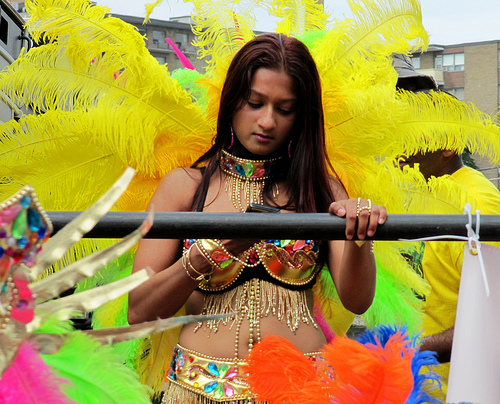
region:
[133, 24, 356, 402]
woman looking at a phone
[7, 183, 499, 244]
black metal pole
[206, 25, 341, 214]
woman with long dark hair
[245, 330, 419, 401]
fuzzy orange feathers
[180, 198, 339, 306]
golden bra with multicolored gems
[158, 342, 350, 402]
gold belt and skirt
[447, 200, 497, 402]
paper zip tied to the pole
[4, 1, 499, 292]
woman wearing a tail piece of yellow feathers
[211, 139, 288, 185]
gold necklace with colorful gems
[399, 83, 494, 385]
person wearing a yellow T-shirt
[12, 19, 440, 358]
the woman is wearing feathers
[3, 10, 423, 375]
the feathers are multi colored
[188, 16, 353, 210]
woman`s hair is reddish brown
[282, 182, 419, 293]
woman is holding a pole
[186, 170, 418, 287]
the pole is black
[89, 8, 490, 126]
a building in the background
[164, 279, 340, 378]
the woman`s stomach is showing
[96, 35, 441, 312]
the woman is looking at her phone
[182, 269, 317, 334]
woman is wearing gold beads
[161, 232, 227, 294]
the woman is wearing bracelets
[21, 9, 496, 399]
Woman dressed in an elaborate costume.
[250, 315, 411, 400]
Orange ornamental plumes.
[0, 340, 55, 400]
Pink ornamental plumes.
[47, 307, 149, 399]
Green ornamental plumes.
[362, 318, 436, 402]
Blue ornamental plumes.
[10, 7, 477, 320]
Yellow ornamental plumes.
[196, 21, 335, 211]
A woman with dark hair.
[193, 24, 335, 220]
A woman with long hair.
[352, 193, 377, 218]
Jewelry around a woman's finger.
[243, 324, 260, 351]
A woman's belly button.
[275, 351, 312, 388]
feathers on the outfit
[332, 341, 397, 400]
feathers on the outfit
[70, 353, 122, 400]
feathers on the outfit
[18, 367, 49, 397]
feathers on the outfit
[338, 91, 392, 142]
feathers on the outfit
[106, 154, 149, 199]
feathers on the outfit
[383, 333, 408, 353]
feathers on the outfit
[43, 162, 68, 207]
feathers on the outfit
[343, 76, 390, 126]
feathers on the outfit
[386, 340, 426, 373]
feathers on the outfit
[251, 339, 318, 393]
feathers on the dancer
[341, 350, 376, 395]
feathers on the dancer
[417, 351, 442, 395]
feathers on the dancer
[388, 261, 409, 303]
feathers on the dancer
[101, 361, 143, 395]
feathers on the dancer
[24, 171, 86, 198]
feathers on the dancer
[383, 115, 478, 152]
feathers on the dancer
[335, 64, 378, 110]
feathers on the dancer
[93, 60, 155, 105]
feathers on the dancer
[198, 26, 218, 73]
feathers on the dancer